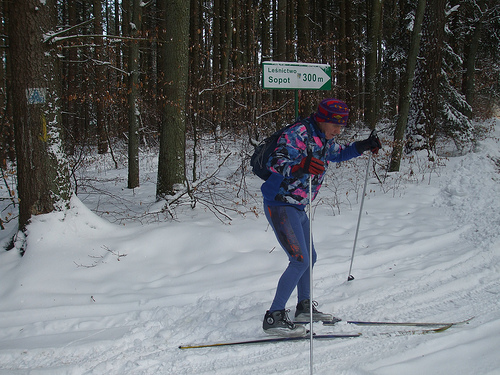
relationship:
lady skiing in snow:
[249, 97, 382, 337] [14, 115, 497, 372]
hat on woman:
[313, 92, 359, 129] [263, 96, 370, 336]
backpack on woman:
[246, 117, 276, 178] [257, 89, 374, 329]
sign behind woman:
[254, 51, 340, 97] [262, 89, 380, 349]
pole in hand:
[298, 170, 324, 372] [300, 155, 325, 176]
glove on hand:
[290, 152, 327, 180] [300, 150, 325, 176]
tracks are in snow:
[10, 301, 126, 350] [9, 228, 496, 369]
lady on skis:
[249, 97, 382, 337] [172, 318, 477, 347]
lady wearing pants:
[249, 97, 382, 337] [247, 202, 323, 314]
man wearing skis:
[250, 96, 383, 340] [177, 312, 477, 352]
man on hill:
[250, 96, 383, 340] [102, 167, 493, 372]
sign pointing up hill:
[254, 51, 340, 97] [319, 142, 498, 368]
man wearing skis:
[248, 96, 381, 342] [172, 318, 477, 347]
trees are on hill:
[3, 6, 252, 212] [5, 153, 498, 365]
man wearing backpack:
[248, 96, 381, 342] [246, 117, 276, 178]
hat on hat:
[313, 92, 359, 129] [314, 99, 349, 140]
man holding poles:
[248, 96, 381, 342] [299, 159, 382, 361]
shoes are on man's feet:
[254, 303, 332, 338] [255, 296, 345, 333]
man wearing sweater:
[248, 96, 381, 342] [267, 115, 349, 208]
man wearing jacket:
[250, 96, 383, 340] [257, 121, 360, 198]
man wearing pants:
[250, 96, 383, 340] [263, 202, 320, 313]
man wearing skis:
[250, 96, 383, 340] [177, 312, 470, 357]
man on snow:
[250, 96, 383, 340] [72, 253, 487, 368]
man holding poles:
[250, 96, 383, 340] [343, 127, 377, 281]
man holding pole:
[250, 96, 383, 340] [307, 170, 312, 371]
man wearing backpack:
[250, 96, 383, 340] [250, 120, 314, 182]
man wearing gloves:
[250, 96, 383, 340] [354, 129, 380, 155]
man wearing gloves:
[250, 96, 383, 340] [294, 152, 327, 180]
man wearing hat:
[250, 96, 383, 340] [316, 95, 359, 126]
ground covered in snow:
[0, 121, 494, 366] [6, 197, 474, 375]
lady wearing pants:
[249, 97, 382, 337] [262, 202, 318, 314]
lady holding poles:
[249, 97, 382, 337] [343, 127, 377, 281]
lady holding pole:
[249, 97, 382, 337] [307, 170, 312, 371]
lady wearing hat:
[249, 97, 382, 337] [311, 90, 356, 130]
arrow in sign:
[261, 63, 327, 83] [254, 51, 340, 97]